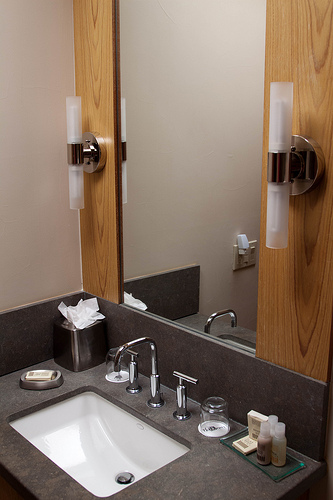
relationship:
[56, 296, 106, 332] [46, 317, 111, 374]
paper towel hanging out of box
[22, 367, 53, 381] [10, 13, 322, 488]
soap in bathroom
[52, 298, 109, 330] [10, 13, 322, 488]
paper towel in bathroom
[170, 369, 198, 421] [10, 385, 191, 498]
fixture at sink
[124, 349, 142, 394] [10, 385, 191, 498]
fixture at sink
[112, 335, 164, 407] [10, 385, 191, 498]
fixture at sink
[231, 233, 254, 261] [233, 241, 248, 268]
light in socket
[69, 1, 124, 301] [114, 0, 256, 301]
wood accent next to mirror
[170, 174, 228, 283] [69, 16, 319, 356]
mirror in frame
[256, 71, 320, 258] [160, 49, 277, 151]
lamp beside mirror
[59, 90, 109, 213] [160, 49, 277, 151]
lamp beside mirror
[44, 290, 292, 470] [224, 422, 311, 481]
toiletries on tray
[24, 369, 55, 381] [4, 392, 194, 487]
soap around sink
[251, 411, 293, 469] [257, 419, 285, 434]
bottles with caps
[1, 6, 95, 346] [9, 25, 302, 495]
wall of bathroom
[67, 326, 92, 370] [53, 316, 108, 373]
reflection on tissue box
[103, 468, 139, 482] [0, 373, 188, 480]
drain in bottom of sink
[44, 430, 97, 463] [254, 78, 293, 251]
reflection on porcelain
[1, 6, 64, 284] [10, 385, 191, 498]
wall beside sink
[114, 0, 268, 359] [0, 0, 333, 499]
mirror in photo